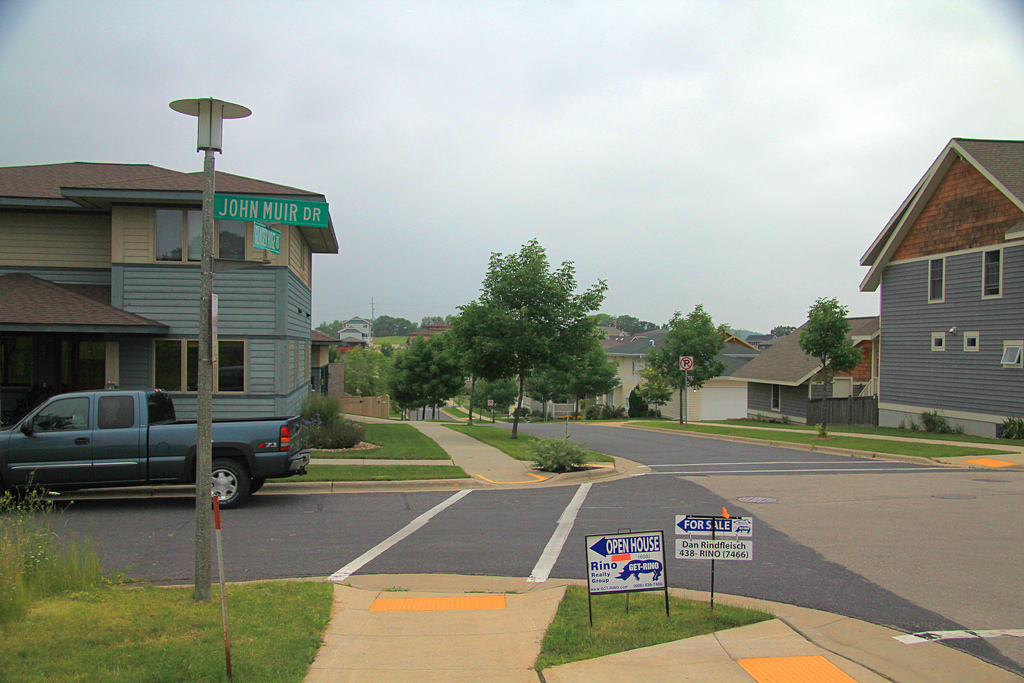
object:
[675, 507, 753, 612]
sign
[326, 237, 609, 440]
trees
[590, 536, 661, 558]
words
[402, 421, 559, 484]
walk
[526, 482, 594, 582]
line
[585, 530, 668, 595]
sign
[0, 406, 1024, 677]
road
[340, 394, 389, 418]
wall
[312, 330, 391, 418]
building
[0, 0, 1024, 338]
clouds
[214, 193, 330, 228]
sign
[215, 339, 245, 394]
window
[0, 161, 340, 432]
building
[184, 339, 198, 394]
window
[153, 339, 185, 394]
window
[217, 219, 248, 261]
window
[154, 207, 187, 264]
window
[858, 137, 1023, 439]
building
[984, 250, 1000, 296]
window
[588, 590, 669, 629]
posts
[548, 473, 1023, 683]
corner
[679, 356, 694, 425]
sign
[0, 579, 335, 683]
ground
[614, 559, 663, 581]
rhino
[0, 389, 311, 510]
truck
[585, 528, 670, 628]
sign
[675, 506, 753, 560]
sign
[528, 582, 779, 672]
grass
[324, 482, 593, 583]
lines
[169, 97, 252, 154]
street light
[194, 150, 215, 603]
pole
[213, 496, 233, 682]
pole